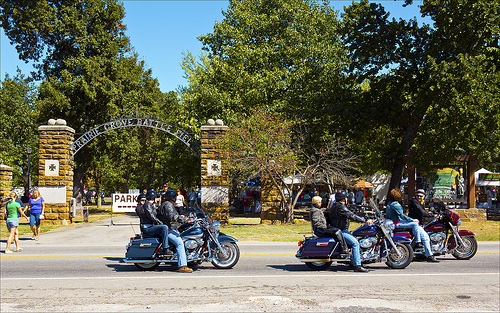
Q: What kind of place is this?
A: It is a park.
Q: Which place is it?
A: It is a park.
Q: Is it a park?
A: Yes, it is a park.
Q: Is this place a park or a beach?
A: It is a park.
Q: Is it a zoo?
A: No, it is a park.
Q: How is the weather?
A: It is clear.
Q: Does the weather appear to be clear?
A: Yes, it is clear.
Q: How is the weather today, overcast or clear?
A: It is clear.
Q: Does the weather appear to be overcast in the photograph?
A: No, it is clear.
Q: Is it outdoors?
A: Yes, it is outdoors.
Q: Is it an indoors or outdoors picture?
A: It is outdoors.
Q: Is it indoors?
A: No, it is outdoors.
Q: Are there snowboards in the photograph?
A: No, there are no snowboards.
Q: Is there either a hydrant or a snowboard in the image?
A: No, there are no snowboards or fire hydrants.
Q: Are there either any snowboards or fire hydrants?
A: No, there are no snowboards or fire hydrants.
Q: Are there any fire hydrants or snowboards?
A: No, there are no snowboards or fire hydrants.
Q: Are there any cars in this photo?
A: No, there are no cars.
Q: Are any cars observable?
A: No, there are no cars.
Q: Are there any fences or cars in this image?
A: No, there are no cars or fences.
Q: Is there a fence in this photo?
A: No, there are no fences.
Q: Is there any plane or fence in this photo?
A: No, there are no fences or airplanes.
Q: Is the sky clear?
A: Yes, the sky is clear.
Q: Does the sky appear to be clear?
A: Yes, the sky is clear.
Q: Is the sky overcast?
A: No, the sky is clear.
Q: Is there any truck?
A: No, there are no trucks.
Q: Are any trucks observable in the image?
A: No, there are no trucks.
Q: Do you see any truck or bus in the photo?
A: No, there are no trucks or buses.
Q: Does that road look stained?
A: Yes, the road is stained.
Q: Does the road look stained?
A: Yes, the road is stained.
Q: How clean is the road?
A: The road is stained.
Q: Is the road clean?
A: No, the road is stained.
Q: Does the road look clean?
A: No, the road is stained.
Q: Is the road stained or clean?
A: The road is stained.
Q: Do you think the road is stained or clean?
A: The road is stained.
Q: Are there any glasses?
A: No, there are no glasses.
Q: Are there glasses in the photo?
A: No, there are no glasses.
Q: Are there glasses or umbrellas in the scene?
A: No, there are no glasses or umbrellas.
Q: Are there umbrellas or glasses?
A: No, there are no glasses or umbrellas.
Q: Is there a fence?
A: No, there are no fences.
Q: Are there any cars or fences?
A: No, there are no fences or cars.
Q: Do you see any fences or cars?
A: No, there are no fences or cars.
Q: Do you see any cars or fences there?
A: No, there are no fences or cars.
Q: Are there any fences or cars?
A: No, there are no fences or cars.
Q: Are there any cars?
A: No, there are no cars.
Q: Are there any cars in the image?
A: No, there are no cars.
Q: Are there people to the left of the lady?
A: Yes, there is a person to the left of the lady.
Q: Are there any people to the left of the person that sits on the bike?
A: Yes, there is a person to the left of the lady.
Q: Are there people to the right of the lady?
A: No, the person is to the left of the lady.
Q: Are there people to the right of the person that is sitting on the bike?
A: No, the person is to the left of the lady.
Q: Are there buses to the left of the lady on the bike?
A: No, there is a person to the left of the lady.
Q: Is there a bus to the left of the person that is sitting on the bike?
A: No, there is a person to the left of the lady.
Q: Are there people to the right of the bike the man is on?
A: No, the person is to the left of the bike.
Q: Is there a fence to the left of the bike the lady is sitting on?
A: No, there is a person to the left of the bike.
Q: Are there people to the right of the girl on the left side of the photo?
A: Yes, there is a person to the right of the girl.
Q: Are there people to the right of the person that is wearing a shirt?
A: Yes, there is a person to the right of the girl.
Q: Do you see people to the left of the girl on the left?
A: No, the person is to the right of the girl.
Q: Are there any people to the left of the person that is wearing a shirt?
A: No, the person is to the right of the girl.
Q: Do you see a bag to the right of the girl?
A: No, there is a person to the right of the girl.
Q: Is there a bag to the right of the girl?
A: No, there is a person to the right of the girl.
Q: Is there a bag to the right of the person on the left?
A: No, there is a person to the right of the girl.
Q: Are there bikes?
A: Yes, there are bikes.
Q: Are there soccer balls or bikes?
A: Yes, there are bikes.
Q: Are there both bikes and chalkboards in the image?
A: No, there are bikes but no chalkboards.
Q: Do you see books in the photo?
A: No, there are no books.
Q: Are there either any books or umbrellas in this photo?
A: No, there are no books or umbrellas.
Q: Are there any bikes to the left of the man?
A: Yes, there are bikes to the left of the man.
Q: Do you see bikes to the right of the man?
A: No, the bikes are to the left of the man.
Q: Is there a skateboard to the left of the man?
A: No, there are bikes to the left of the man.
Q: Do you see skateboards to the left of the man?
A: No, there are bikes to the left of the man.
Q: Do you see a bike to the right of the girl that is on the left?
A: Yes, there are bikes to the right of the girl.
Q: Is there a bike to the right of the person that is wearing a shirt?
A: Yes, there are bikes to the right of the girl.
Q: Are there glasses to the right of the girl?
A: No, there are bikes to the right of the girl.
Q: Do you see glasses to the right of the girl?
A: No, there are bikes to the right of the girl.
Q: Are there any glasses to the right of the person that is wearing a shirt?
A: No, there are bikes to the right of the girl.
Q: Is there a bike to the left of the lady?
A: Yes, there are bikes to the left of the lady.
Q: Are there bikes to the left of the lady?
A: Yes, there are bikes to the left of the lady.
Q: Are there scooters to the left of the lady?
A: No, there are bikes to the left of the lady.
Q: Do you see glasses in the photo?
A: No, there are no glasses.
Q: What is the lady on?
A: The lady is on the bike.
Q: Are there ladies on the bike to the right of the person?
A: Yes, there is a lady on the bike.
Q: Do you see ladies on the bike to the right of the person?
A: Yes, there is a lady on the bike.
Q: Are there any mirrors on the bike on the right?
A: No, there is a lady on the bike.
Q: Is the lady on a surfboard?
A: No, the lady is on the bike.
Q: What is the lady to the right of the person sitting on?
A: The lady is sitting on the bike.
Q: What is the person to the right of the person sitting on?
A: The lady is sitting on the bike.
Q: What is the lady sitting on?
A: The lady is sitting on the bike.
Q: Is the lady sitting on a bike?
A: Yes, the lady is sitting on a bike.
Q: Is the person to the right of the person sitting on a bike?
A: Yes, the lady is sitting on a bike.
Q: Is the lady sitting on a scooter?
A: No, the lady is sitting on a bike.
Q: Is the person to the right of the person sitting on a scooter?
A: No, the lady is sitting on a bike.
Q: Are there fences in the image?
A: No, there are no fences.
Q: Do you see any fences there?
A: No, there are no fences.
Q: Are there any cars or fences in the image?
A: No, there are no fences or cars.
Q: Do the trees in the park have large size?
A: Yes, the trees are large.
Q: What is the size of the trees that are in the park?
A: The trees are large.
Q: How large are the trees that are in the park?
A: The trees are large.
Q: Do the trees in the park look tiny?
A: No, the trees are large.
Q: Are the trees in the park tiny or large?
A: The trees are large.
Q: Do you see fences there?
A: No, there are no fences.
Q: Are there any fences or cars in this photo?
A: No, there are no fences or cars.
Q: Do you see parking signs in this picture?
A: Yes, there is a parking sign.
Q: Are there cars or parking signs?
A: Yes, there is a parking sign.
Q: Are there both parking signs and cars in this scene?
A: No, there is a parking sign but no cars.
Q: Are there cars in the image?
A: No, there are no cars.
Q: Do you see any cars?
A: No, there are no cars.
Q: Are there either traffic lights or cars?
A: No, there are no cars or traffic lights.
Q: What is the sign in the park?
A: The sign is a parking sign.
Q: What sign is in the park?
A: The sign is a parking sign.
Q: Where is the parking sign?
A: The parking sign is in the park.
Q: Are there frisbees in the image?
A: No, there are no frisbees.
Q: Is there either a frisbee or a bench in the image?
A: No, there are no frisbees or benches.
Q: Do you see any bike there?
A: Yes, there is a bike.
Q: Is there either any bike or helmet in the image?
A: Yes, there is a bike.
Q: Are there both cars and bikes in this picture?
A: No, there is a bike but no cars.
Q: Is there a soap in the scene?
A: No, there are no soaps.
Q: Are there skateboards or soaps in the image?
A: No, there are no soaps or skateboards.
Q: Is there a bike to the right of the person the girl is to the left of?
A: Yes, there is a bike to the right of the person.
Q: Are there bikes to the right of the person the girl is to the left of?
A: Yes, there is a bike to the right of the person.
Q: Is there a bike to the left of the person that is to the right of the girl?
A: No, the bike is to the right of the person.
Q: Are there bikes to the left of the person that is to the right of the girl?
A: No, the bike is to the right of the person.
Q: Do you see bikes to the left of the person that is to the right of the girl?
A: No, the bike is to the right of the person.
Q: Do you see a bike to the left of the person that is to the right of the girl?
A: No, the bike is to the right of the person.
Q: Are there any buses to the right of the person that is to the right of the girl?
A: No, there is a bike to the right of the person.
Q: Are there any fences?
A: No, there are no fences.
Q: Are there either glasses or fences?
A: No, there are no fences or glasses.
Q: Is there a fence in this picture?
A: No, there are no fences.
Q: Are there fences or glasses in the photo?
A: No, there are no fences or glasses.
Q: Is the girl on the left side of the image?
A: Yes, the girl is on the left of the image.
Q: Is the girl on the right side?
A: No, the girl is on the left of the image.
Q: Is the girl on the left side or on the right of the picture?
A: The girl is on the left of the image.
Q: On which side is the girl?
A: The girl is on the left of the image.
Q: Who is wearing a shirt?
A: The girl is wearing a shirt.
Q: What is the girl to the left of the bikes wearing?
A: The girl is wearing a shirt.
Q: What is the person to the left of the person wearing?
A: The girl is wearing a shirt.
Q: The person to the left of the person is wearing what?
A: The girl is wearing a shirt.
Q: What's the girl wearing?
A: The girl is wearing a shirt.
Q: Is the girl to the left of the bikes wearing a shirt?
A: Yes, the girl is wearing a shirt.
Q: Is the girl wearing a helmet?
A: No, the girl is wearing a shirt.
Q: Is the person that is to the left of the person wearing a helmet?
A: No, the girl is wearing a shirt.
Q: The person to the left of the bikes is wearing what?
A: The girl is wearing a shirt.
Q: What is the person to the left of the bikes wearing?
A: The girl is wearing a shirt.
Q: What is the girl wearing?
A: The girl is wearing a shirt.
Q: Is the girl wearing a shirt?
A: Yes, the girl is wearing a shirt.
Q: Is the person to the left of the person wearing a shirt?
A: Yes, the girl is wearing a shirt.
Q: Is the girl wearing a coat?
A: No, the girl is wearing a shirt.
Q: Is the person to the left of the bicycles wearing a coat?
A: No, the girl is wearing a shirt.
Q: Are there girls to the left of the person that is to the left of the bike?
A: Yes, there is a girl to the left of the person.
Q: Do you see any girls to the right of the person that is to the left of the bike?
A: No, the girl is to the left of the person.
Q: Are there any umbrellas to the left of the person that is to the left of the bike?
A: No, there is a girl to the left of the person.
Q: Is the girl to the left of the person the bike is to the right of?
A: Yes, the girl is to the left of the person.